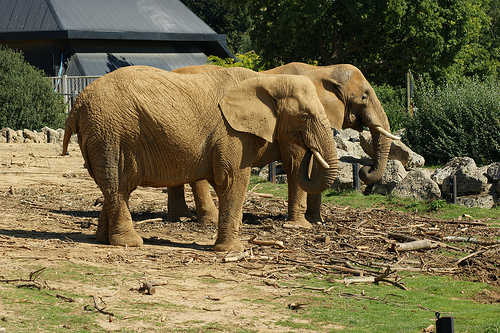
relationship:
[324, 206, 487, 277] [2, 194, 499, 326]
branches on ground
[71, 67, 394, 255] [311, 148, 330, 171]
elephants have tusks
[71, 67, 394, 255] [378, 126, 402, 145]
elephants have tusks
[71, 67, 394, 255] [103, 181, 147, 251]
elephant has leg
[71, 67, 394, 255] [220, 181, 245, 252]
elephant has leg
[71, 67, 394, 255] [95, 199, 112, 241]
elephant has leg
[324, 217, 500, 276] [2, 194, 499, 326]
branches on ground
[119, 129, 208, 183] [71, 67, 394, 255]
stomach of elephant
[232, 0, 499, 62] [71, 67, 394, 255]
trees behind elephants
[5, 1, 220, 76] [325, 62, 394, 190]
building behind elephant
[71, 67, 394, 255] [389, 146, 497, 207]
elephants amongst rocks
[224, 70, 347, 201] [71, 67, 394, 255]
head of elephant